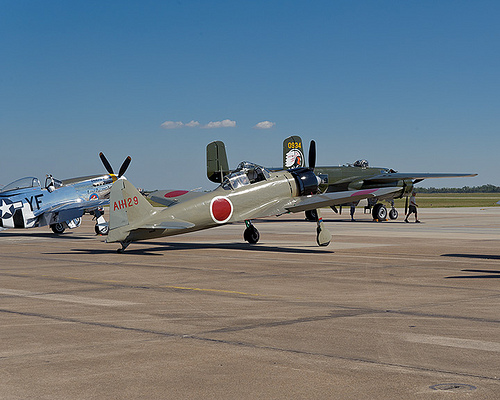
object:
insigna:
[112, 196, 139, 212]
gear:
[315, 220, 332, 247]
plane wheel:
[244, 227, 261, 244]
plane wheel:
[50, 221, 67, 233]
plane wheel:
[94, 221, 109, 235]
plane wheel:
[315, 230, 333, 246]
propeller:
[97, 151, 133, 178]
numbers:
[287, 141, 301, 149]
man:
[403, 190, 421, 224]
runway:
[9, 206, 499, 396]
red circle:
[210, 194, 235, 225]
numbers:
[112, 195, 139, 212]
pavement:
[89, 273, 190, 314]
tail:
[281, 135, 305, 173]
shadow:
[40, 241, 332, 261]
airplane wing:
[285, 185, 404, 209]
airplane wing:
[146, 189, 207, 207]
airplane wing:
[48, 196, 110, 212]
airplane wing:
[366, 171, 479, 181]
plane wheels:
[389, 207, 399, 220]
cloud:
[255, 120, 276, 130]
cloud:
[154, 117, 199, 134]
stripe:
[1, 269, 248, 294]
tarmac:
[0, 202, 497, 398]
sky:
[2, 2, 497, 189]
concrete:
[1, 205, 498, 398]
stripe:
[350, 187, 379, 202]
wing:
[297, 186, 400, 207]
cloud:
[206, 118, 237, 128]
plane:
[1, 151, 134, 239]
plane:
[204, 133, 479, 221]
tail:
[103, 178, 193, 240]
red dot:
[208, 194, 234, 224]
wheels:
[369, 203, 389, 222]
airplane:
[104, 134, 403, 254]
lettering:
[113, 196, 140, 212]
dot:
[209, 195, 234, 225]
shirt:
[409, 196, 417, 207]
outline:
[210, 195, 234, 224]